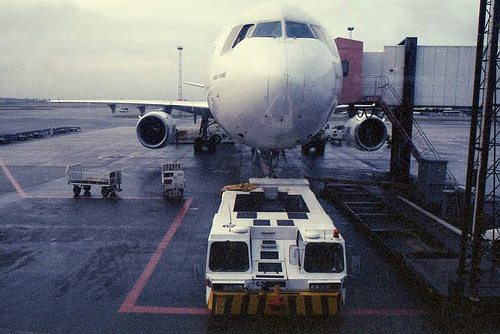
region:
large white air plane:
[212, 25, 354, 147]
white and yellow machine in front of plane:
[210, 158, 350, 324]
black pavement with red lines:
[112, 187, 422, 325]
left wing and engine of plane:
[30, 58, 213, 183]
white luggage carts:
[65, 149, 202, 224]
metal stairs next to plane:
[367, 63, 462, 218]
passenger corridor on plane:
[320, 30, 479, 122]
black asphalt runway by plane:
[29, 93, 132, 291]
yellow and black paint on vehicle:
[200, 288, 376, 321]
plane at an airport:
[70, 15, 416, 175]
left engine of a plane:
[123, 107, 185, 162]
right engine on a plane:
[340, 100, 391, 160]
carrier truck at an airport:
[197, 160, 367, 320]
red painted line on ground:
[120, 235, 176, 320]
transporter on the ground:
[60, 157, 130, 203]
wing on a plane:
[45, 86, 211, 116]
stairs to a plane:
[380, 86, 460, 201]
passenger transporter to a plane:
[345, 35, 490, 112]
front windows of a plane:
[217, 15, 335, 60]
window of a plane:
[228, 25, 240, 45]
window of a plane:
[236, 19, 255, 49]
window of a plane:
[253, 23, 265, 32]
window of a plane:
[255, 23, 276, 35]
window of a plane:
[292, 15, 303, 42]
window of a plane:
[301, 20, 331, 53]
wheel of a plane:
[181, 131, 223, 158]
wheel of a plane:
[295, 130, 340, 155]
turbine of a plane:
[128, 107, 178, 154]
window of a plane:
[220, 17, 252, 52]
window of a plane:
[258, 11, 281, 40]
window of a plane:
[273, 10, 317, 42]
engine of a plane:
[124, 107, 191, 154]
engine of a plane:
[343, 114, 393, 156]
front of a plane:
[202, 15, 352, 132]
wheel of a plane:
[189, 135, 226, 154]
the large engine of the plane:
[132, 108, 175, 150]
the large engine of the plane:
[342, 113, 386, 153]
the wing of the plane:
[45, 97, 213, 117]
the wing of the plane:
[335, 98, 376, 112]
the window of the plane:
[220, 23, 237, 50]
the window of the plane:
[235, 23, 255, 47]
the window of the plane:
[254, 18, 285, 40]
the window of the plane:
[285, 17, 314, 41]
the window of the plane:
[311, 20, 335, 55]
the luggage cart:
[61, 162, 121, 198]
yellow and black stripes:
[216, 288, 337, 320]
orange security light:
[333, 228, 340, 238]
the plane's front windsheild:
[253, 15, 313, 42]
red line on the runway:
[116, 261, 156, 331]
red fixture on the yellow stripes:
[266, 280, 284, 315]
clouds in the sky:
[103, 38, 133, 74]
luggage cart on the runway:
[54, 160, 134, 204]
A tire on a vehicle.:
[95, 185, 112, 199]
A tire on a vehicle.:
[166, 188, 173, 198]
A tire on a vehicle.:
[176, 188, 182, 197]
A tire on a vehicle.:
[163, 185, 165, 195]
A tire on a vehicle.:
[190, 137, 202, 157]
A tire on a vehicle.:
[209, 136, 214, 155]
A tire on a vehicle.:
[70, 185, 81, 195]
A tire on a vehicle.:
[84, 182, 94, 194]